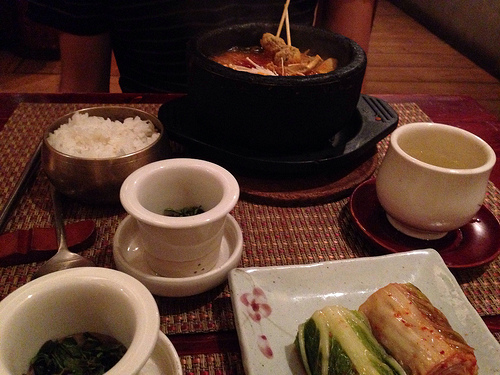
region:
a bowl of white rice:
[41, 103, 161, 190]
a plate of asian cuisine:
[231, 259, 492, 370]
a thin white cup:
[119, 153, 239, 291]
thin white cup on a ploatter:
[116, 160, 244, 290]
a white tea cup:
[381, 113, 491, 243]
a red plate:
[343, 187, 497, 262]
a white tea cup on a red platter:
[332, 130, 494, 264]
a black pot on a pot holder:
[151, 15, 392, 182]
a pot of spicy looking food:
[201, 20, 346, 95]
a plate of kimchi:
[292, 283, 460, 368]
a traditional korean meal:
[6, 3, 490, 362]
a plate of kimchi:
[245, 255, 472, 373]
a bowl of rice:
[40, 106, 192, 192]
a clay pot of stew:
[188, 16, 386, 141]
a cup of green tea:
[371, 89, 477, 224]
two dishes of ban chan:
[27, 161, 254, 358]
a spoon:
[30, 198, 112, 288]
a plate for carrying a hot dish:
[153, 93, 439, 179]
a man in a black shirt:
[45, 5, 415, 119]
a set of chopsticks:
[0, 116, 62, 231]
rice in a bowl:
[48, 93, 160, 187]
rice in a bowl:
[45, 94, 131, 185]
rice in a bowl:
[48, 94, 138, 171]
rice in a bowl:
[61, 91, 144, 193]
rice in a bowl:
[39, 95, 124, 182]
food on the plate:
[291, 247, 443, 372]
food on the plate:
[285, 268, 457, 373]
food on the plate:
[280, 264, 479, 372]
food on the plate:
[290, 280, 442, 374]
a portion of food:
[205, 18, 357, 116]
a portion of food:
[151, 164, 236, 259]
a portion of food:
[74, 102, 159, 167]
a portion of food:
[58, 105, 119, 186]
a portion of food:
[342, 264, 457, 372]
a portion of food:
[303, 276, 369, 373]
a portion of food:
[351, 262, 441, 373]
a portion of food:
[303, 290, 388, 369]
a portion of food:
[208, 22, 277, 107]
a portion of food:
[265, 14, 362, 124]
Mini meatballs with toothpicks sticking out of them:
[261, 0, 303, 65]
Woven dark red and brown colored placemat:
[0, 101, 498, 373]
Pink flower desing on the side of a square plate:
[240, 285, 274, 359]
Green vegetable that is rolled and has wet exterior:
[294, 303, 406, 373]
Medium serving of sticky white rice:
[43, 109, 158, 158]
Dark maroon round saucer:
[348, 178, 498, 270]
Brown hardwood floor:
[0, 0, 498, 94]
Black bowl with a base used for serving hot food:
[158, 18, 398, 179]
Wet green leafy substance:
[25, 328, 126, 374]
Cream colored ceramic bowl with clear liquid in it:
[373, 120, 497, 242]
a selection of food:
[11, 10, 496, 373]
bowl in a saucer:
[117, 151, 247, 302]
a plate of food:
[230, 238, 467, 374]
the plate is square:
[209, 225, 496, 359]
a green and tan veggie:
[300, 275, 394, 374]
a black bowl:
[180, 16, 387, 146]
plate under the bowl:
[143, 91, 408, 183]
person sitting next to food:
[34, 5, 366, 102]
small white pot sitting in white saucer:
[111, 155, 244, 297]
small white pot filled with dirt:
[5, 263, 183, 370]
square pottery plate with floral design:
[236, 243, 498, 372]